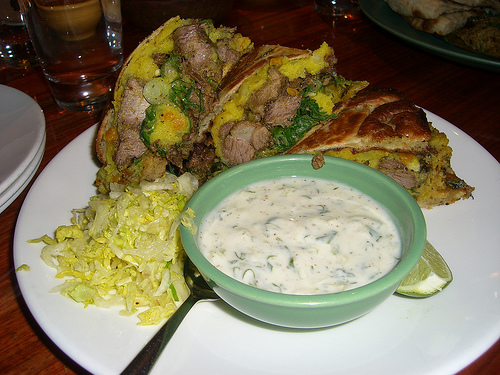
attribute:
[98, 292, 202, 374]
spoon — silver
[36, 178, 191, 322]
food — yellow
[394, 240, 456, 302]
lemon — cut, halved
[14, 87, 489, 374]
plate — white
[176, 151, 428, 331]
bowl — green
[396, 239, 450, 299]
orange — quartered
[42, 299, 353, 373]
plate — white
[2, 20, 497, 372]
table — brown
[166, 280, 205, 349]
spoon — silvery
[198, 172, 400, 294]
soup — white, thick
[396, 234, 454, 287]
limon — green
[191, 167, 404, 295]
sauce — yogurt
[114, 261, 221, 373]
spoon — silver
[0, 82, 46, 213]
plates — white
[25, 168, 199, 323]
cabbage — green